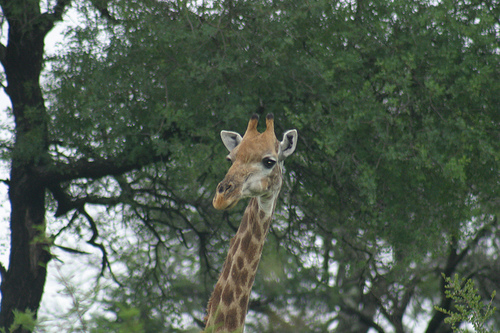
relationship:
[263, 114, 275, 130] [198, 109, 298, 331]
ear on a giraffe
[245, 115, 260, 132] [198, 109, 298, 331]
ear on a giraffe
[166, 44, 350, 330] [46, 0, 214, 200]
giraffe/trees standing in front of trees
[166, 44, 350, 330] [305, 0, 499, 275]
giraffe/trees standing in front of trees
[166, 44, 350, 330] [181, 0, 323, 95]
giraffe/trees standing in front of trees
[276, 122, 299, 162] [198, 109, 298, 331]
ear of giraffe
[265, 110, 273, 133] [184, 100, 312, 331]
horn of giraffe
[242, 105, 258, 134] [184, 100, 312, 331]
horn of giraffe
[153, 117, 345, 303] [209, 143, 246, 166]
giraffe has eyes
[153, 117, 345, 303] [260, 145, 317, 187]
giraffe has eyes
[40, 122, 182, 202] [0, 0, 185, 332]
branch on tree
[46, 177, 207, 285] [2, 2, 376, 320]
branch on tree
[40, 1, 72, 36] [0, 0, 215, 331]
branch on tree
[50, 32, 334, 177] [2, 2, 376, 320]
branch on tree